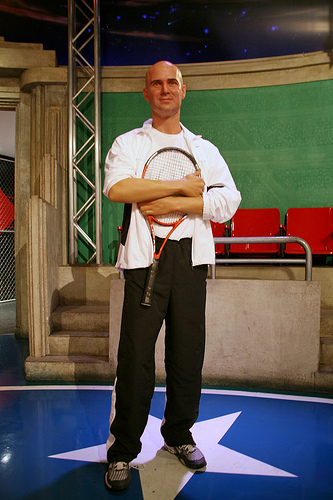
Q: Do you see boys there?
A: No, there are no boys.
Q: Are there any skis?
A: No, there are no skis.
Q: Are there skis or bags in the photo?
A: No, there are no skis or bags.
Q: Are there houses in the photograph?
A: No, there are no houses.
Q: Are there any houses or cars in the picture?
A: No, there are no houses or cars.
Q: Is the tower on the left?
A: Yes, the tower is on the left of the image.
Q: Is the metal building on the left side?
A: Yes, the tower is on the left of the image.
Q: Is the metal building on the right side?
A: No, the tower is on the left of the image.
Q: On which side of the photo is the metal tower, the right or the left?
A: The tower is on the left of the image.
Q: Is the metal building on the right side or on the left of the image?
A: The tower is on the left of the image.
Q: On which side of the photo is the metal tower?
A: The tower is on the left of the image.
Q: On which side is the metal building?
A: The tower is on the left of the image.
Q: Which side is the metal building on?
A: The tower is on the left of the image.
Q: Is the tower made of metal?
A: Yes, the tower is made of metal.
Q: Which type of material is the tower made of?
A: The tower is made of metal.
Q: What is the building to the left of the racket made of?
A: The tower is made of metal.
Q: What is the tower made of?
A: The tower is made of metal.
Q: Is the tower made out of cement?
A: No, the tower is made of metal.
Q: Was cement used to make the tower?
A: No, the tower is made of metal.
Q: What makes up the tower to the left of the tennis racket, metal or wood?
A: The tower is made of metal.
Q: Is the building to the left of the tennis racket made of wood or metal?
A: The tower is made of metal.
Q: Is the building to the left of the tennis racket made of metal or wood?
A: The tower is made of metal.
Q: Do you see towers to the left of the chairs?
A: Yes, there is a tower to the left of the chairs.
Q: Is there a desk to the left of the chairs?
A: No, there is a tower to the left of the chairs.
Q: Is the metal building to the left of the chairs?
A: Yes, the tower is to the left of the chairs.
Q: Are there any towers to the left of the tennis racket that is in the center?
A: Yes, there is a tower to the left of the tennis racket.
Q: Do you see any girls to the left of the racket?
A: No, there is a tower to the left of the racket.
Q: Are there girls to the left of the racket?
A: No, there is a tower to the left of the racket.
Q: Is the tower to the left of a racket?
A: Yes, the tower is to the left of a racket.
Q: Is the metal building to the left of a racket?
A: Yes, the tower is to the left of a racket.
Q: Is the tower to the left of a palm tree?
A: No, the tower is to the left of a racket.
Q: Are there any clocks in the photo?
A: No, there are no clocks.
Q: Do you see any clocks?
A: No, there are no clocks.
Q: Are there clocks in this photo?
A: No, there are no clocks.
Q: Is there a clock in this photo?
A: No, there are no clocks.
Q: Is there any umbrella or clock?
A: No, there are no clocks or umbrellas.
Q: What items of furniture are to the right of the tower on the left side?
A: The pieces of furniture are chairs.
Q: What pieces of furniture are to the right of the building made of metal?
A: The pieces of furniture are chairs.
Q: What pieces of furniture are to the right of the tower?
A: The pieces of furniture are chairs.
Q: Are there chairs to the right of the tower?
A: Yes, there are chairs to the right of the tower.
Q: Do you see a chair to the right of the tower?
A: Yes, there are chairs to the right of the tower.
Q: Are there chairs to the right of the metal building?
A: Yes, there are chairs to the right of the tower.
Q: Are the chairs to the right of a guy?
A: No, the chairs are to the right of a tower.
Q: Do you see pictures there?
A: No, there are no pictures.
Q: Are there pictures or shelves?
A: No, there are no pictures or shelves.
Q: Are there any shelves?
A: No, there are no shelves.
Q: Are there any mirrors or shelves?
A: No, there are no shelves or mirrors.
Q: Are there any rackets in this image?
A: Yes, there is a racket.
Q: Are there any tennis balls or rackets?
A: Yes, there is a racket.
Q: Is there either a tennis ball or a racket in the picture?
A: Yes, there is a racket.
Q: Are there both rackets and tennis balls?
A: No, there is a racket but no tennis balls.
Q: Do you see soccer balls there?
A: No, there are no soccer balls.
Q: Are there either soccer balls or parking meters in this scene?
A: No, there are no soccer balls or parking meters.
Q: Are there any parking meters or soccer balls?
A: No, there are no soccer balls or parking meters.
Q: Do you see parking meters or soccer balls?
A: No, there are no soccer balls or parking meters.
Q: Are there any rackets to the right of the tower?
A: Yes, there is a racket to the right of the tower.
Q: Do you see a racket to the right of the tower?
A: Yes, there is a racket to the right of the tower.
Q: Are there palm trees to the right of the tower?
A: No, there is a racket to the right of the tower.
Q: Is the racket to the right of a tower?
A: Yes, the racket is to the right of a tower.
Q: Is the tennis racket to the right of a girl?
A: No, the tennis racket is to the right of a tower.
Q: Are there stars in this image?
A: Yes, there is a star.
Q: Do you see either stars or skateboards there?
A: Yes, there is a star.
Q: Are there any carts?
A: No, there are no carts.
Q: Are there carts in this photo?
A: No, there are no carts.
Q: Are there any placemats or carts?
A: No, there are no carts or placemats.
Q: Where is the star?
A: The star is on the floor.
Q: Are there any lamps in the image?
A: No, there are no lamps.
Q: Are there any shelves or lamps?
A: No, there are no lamps or shelves.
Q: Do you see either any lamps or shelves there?
A: No, there are no lamps or shelves.